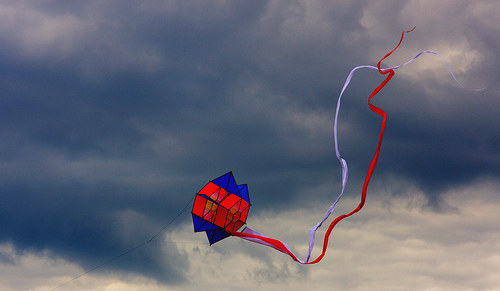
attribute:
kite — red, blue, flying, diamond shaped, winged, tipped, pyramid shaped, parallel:
[192, 28, 459, 271]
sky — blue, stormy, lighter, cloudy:
[2, 4, 498, 286]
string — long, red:
[202, 232, 293, 288]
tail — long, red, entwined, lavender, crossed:
[232, 26, 482, 271]